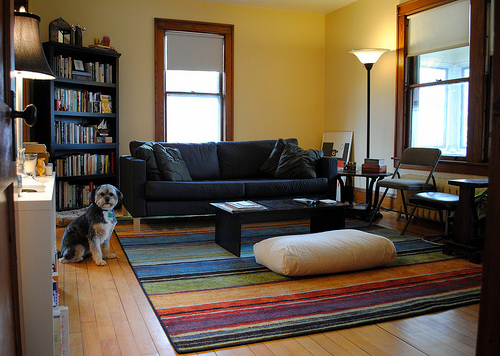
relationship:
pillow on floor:
[252, 229, 395, 276] [56, 206, 485, 355]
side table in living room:
[340, 169, 389, 219] [0, 0, 498, 353]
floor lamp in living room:
[352, 49, 394, 223] [0, 0, 498, 353]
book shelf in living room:
[30, 42, 120, 210] [0, 0, 498, 353]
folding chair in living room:
[374, 149, 441, 233] [0, 0, 498, 353]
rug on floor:
[114, 217, 483, 352] [56, 206, 485, 355]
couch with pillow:
[119, 138, 335, 225] [156, 145, 197, 181]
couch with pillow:
[119, 138, 335, 225] [136, 143, 163, 178]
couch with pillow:
[119, 138, 335, 225] [274, 144, 318, 177]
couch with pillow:
[119, 138, 335, 225] [264, 138, 285, 175]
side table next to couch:
[340, 169, 389, 219] [119, 138, 335, 225]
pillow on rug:
[252, 229, 395, 276] [114, 217, 483, 352]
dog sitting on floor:
[61, 185, 124, 268] [56, 206, 485, 355]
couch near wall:
[119, 138, 335, 225] [10, 4, 496, 213]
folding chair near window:
[374, 149, 441, 233] [395, 2, 489, 175]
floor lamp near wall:
[352, 49, 394, 223] [10, 4, 496, 213]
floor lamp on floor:
[352, 49, 394, 223] [56, 206, 485, 355]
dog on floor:
[61, 185, 124, 268] [56, 206, 485, 355]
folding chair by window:
[374, 149, 441, 233] [395, 2, 489, 175]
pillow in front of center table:
[252, 229, 395, 276] [212, 201, 348, 256]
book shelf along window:
[30, 42, 120, 210] [395, 2, 489, 175]